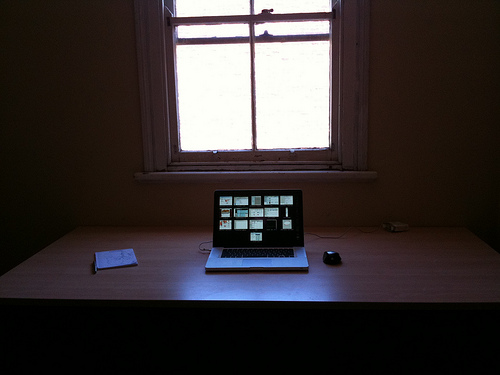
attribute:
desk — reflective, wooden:
[0, 228, 500, 372]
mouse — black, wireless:
[324, 250, 344, 267]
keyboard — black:
[221, 247, 295, 257]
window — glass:
[174, 0, 333, 153]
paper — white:
[94, 247, 139, 271]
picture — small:
[250, 232, 263, 242]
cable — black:
[304, 223, 387, 239]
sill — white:
[135, 0, 377, 181]